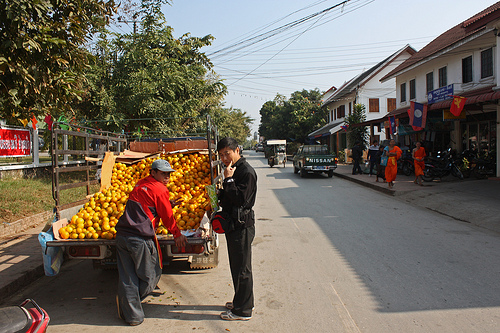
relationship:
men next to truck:
[110, 132, 265, 325] [41, 106, 224, 272]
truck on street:
[41, 106, 224, 272] [27, 150, 496, 330]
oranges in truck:
[69, 148, 206, 235] [41, 106, 224, 272]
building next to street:
[382, 7, 499, 177] [27, 150, 496, 330]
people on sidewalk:
[352, 134, 431, 189] [336, 156, 498, 235]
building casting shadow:
[382, 7, 499, 177] [270, 163, 498, 314]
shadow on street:
[270, 163, 498, 314] [27, 150, 496, 330]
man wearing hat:
[111, 151, 187, 323] [147, 156, 176, 176]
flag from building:
[436, 90, 469, 118] [382, 7, 499, 177]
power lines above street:
[183, 5, 372, 81] [27, 150, 496, 330]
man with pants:
[111, 151, 187, 323] [114, 233, 164, 318]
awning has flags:
[386, 88, 498, 119] [385, 92, 469, 131]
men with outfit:
[212, 137, 256, 323] [210, 156, 263, 319]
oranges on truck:
[69, 148, 206, 235] [41, 106, 224, 272]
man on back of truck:
[111, 151, 187, 323] [41, 106, 224, 272]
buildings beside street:
[296, 0, 498, 177] [27, 150, 496, 330]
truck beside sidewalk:
[289, 140, 341, 179] [336, 156, 498, 235]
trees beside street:
[115, 29, 258, 143] [27, 150, 496, 330]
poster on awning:
[420, 80, 454, 100] [386, 88, 498, 119]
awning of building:
[386, 88, 498, 119] [382, 7, 499, 177]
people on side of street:
[352, 134, 431, 189] [27, 150, 496, 330]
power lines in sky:
[183, 5, 372, 81] [172, 2, 491, 105]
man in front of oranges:
[111, 151, 187, 323] [69, 148, 206, 235]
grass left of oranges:
[0, 165, 99, 215] [69, 148, 206, 235]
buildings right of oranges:
[296, 0, 498, 177] [69, 148, 206, 235]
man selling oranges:
[111, 151, 187, 323] [69, 148, 206, 235]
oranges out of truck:
[69, 148, 206, 235] [41, 106, 224, 272]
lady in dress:
[379, 138, 399, 186] [383, 146, 406, 183]